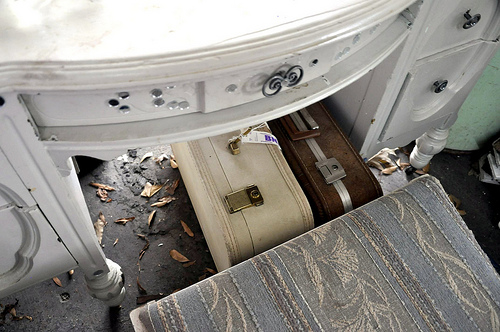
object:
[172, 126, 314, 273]
suitcase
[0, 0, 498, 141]
vanity table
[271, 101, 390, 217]
suitcase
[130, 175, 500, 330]
bench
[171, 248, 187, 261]
leaf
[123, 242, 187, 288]
floor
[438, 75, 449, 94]
drawer pull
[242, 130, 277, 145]
tag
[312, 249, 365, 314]
pattern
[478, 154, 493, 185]
block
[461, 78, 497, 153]
wall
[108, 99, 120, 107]
dot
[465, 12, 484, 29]
drawer pull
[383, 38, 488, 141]
drawer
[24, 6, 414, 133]
drawer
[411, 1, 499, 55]
drawer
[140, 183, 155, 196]
leaf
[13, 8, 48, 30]
light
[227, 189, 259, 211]
latch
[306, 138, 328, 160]
band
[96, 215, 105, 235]
leaf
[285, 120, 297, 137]
handle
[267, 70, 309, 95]
drawer pull